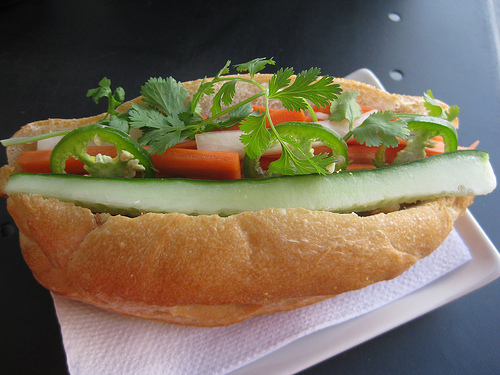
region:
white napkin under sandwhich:
[68, 325, 126, 372]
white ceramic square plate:
[332, 306, 442, 357]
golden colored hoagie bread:
[111, 238, 370, 327]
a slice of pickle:
[99, 179, 497, 191]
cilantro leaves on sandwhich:
[144, 58, 462, 139]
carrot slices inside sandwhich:
[18, 127, 387, 177]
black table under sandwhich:
[257, 15, 467, 74]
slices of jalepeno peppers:
[57, 126, 454, 188]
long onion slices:
[156, 103, 415, 159]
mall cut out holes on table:
[374, 61, 442, 103]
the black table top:
[403, 317, 497, 367]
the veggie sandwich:
[13, 62, 466, 319]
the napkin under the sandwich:
[62, 316, 214, 353]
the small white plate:
[45, 64, 499, 369]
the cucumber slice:
[2, 159, 497, 219]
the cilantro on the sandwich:
[108, 55, 340, 193]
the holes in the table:
[385, 7, 404, 82]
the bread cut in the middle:
[9, 87, 488, 322]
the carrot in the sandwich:
[25, 135, 245, 187]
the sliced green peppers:
[35, 116, 468, 178]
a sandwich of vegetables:
[0, 47, 492, 332]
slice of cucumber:
[5, 145, 499, 210]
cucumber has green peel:
[3, 146, 498, 224]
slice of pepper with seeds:
[26, 115, 167, 186]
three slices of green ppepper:
[43, 105, 460, 188]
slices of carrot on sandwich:
[18, 135, 248, 194]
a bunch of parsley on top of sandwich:
[106, 45, 344, 180]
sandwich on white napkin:
[10, 50, 496, 371]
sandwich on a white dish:
[35, 35, 495, 370]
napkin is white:
[33, 243, 473, 371]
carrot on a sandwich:
[20, 143, 240, 178]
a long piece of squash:
[0, 141, 498, 224]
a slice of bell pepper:
[45, 125, 165, 187]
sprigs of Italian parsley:
[129, 61, 341, 154]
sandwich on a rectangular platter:
[20, 53, 497, 373]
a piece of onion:
[196, 123, 288, 159]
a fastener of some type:
[386, 62, 408, 88]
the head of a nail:
[388, 49, 417, 94]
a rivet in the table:
[379, 52, 422, 92]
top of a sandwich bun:
[12, 193, 474, 323]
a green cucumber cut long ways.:
[5, 149, 495, 214]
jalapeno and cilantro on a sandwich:
[241, 121, 349, 181]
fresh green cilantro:
[84, 55, 339, 132]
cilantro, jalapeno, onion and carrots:
[134, 70, 344, 174]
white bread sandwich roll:
[25, 216, 484, 331]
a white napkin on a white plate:
[44, 219, 482, 374]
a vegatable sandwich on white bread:
[4, 54, 497, 329]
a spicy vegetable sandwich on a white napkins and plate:
[0, 55, 497, 366]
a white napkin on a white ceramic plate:
[50, 277, 492, 374]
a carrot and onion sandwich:
[12, 120, 459, 173]